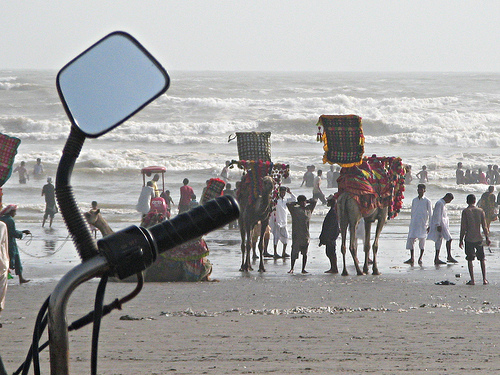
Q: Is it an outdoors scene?
A: Yes, it is outdoors.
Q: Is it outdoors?
A: Yes, it is outdoors.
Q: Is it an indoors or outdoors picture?
A: It is outdoors.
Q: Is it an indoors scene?
A: No, it is outdoors.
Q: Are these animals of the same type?
A: Yes, all the animals are camels.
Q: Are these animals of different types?
A: No, all the animals are camels.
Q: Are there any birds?
A: No, there are no birds.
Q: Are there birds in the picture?
A: No, there are no birds.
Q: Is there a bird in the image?
A: No, there are no birds.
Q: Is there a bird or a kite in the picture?
A: No, there are no birds or kites.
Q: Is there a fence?
A: No, there are no fences.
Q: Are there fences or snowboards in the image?
A: No, there are no fences or snowboards.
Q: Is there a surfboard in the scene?
A: No, there are no surfboards.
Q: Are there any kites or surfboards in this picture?
A: No, there are no surfboards or kites.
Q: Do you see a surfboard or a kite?
A: No, there are no surfboards or kites.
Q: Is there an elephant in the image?
A: No, there are no elephants.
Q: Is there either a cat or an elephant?
A: No, there are no elephants or cats.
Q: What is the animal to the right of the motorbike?
A: The animal is a camel.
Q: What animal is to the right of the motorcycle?
A: The animal is a camel.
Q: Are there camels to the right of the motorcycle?
A: Yes, there is a camel to the right of the motorcycle.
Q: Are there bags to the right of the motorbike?
A: No, there is a camel to the right of the motorbike.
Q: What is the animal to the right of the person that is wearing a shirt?
A: The animal is a camel.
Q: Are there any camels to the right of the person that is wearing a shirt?
A: Yes, there is a camel to the right of the person.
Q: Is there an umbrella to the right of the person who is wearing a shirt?
A: No, there is a camel to the right of the person.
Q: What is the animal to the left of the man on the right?
A: The animal is a camel.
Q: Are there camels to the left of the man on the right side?
A: Yes, there is a camel to the left of the man.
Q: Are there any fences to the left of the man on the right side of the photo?
A: No, there is a camel to the left of the man.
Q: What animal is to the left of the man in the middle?
A: The animal is a camel.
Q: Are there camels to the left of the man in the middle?
A: Yes, there is a camel to the left of the man.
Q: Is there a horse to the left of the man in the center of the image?
A: No, there is a camel to the left of the man.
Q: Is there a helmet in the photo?
A: No, there are no helmets.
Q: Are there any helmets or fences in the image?
A: No, there are no helmets or fences.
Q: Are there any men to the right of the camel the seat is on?
A: Yes, there is a man to the right of the camel.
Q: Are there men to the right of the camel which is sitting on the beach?
A: Yes, there is a man to the right of the camel.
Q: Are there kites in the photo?
A: No, there are no kites.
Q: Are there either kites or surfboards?
A: No, there are no kites or surfboards.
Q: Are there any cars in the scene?
A: No, there are no cars.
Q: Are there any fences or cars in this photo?
A: No, there are no cars or fences.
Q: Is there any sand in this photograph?
A: Yes, there is sand.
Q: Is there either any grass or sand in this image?
A: Yes, there is sand.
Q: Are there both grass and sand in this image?
A: No, there is sand but no grass.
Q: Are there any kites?
A: No, there are no kites.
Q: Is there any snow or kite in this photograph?
A: No, there are no kites or snow.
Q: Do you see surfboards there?
A: No, there are no surfboards.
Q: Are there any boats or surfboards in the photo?
A: No, there are no surfboards or boats.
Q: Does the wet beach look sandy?
A: Yes, the beach is sandy.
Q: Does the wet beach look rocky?
A: No, the beach is sandy.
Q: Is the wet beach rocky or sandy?
A: The beach is sandy.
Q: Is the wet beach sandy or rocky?
A: The beach is sandy.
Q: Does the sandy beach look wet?
A: Yes, the beach is wet.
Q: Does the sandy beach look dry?
A: No, the beach is wet.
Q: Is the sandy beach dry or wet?
A: The beach is wet.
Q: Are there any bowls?
A: No, there are no bowls.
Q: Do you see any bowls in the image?
A: No, there are no bowls.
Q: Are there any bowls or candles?
A: No, there are no bowls or candles.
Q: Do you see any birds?
A: No, there are no birds.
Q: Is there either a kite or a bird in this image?
A: No, there are no birds or kites.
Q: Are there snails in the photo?
A: No, there are no snails.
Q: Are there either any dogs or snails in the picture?
A: No, there are no snails or dogs.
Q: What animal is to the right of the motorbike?
A: The animal is a camel.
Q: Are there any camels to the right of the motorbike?
A: Yes, there is a camel to the right of the motorbike.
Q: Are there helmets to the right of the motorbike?
A: No, there is a camel to the right of the motorbike.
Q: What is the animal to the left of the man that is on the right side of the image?
A: The animal is a camel.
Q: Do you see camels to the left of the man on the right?
A: Yes, there is a camel to the left of the man.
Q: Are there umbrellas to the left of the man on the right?
A: No, there is a camel to the left of the man.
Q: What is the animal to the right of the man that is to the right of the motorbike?
A: The animal is a camel.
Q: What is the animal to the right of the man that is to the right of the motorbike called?
A: The animal is a camel.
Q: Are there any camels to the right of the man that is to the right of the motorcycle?
A: Yes, there is a camel to the right of the man.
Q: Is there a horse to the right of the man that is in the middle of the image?
A: No, there is a camel to the right of the man.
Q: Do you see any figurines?
A: No, there are no figurines.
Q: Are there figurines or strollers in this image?
A: No, there are no figurines or strollers.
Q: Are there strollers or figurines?
A: No, there are no figurines or strollers.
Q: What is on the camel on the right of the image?
A: The seat is on the camel.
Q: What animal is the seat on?
A: The seat is on the camel.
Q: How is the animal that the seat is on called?
A: The animal is a camel.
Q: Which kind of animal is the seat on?
A: The seat is on the camel.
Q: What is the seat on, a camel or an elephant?
A: The seat is on a camel.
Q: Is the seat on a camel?
A: Yes, the seat is on a camel.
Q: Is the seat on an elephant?
A: No, the seat is on a camel.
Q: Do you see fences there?
A: No, there are no fences.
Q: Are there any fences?
A: No, there are no fences.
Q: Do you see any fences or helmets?
A: No, there are no fences or helmets.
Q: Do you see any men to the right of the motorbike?
A: Yes, there is a man to the right of the motorbike.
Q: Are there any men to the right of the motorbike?
A: Yes, there is a man to the right of the motorbike.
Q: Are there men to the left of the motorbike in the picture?
A: No, the man is to the right of the motorbike.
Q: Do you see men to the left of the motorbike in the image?
A: No, the man is to the right of the motorbike.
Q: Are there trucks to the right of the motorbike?
A: No, there is a man to the right of the motorbike.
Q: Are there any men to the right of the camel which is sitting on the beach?
A: Yes, there is a man to the right of the camel.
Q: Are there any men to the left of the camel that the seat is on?
A: Yes, there is a man to the left of the camel.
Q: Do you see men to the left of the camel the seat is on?
A: Yes, there is a man to the left of the camel.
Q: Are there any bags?
A: No, there are no bags.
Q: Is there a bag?
A: No, there are no bags.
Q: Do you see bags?
A: No, there are no bags.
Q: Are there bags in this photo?
A: No, there are no bags.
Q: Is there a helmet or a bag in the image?
A: No, there are no bags or helmets.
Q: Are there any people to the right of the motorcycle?
A: Yes, there is a person to the right of the motorcycle.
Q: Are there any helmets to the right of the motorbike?
A: No, there is a person to the right of the motorbike.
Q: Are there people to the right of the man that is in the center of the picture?
A: Yes, there is a person to the right of the man.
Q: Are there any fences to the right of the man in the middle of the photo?
A: No, there is a person to the right of the man.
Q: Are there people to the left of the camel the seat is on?
A: Yes, there is a person to the left of the camel.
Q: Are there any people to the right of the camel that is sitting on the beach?
A: Yes, there is a person to the right of the camel.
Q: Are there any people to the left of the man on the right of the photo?
A: Yes, there is a person to the left of the man.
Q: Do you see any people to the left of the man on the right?
A: Yes, there is a person to the left of the man.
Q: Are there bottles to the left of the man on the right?
A: No, there is a person to the left of the man.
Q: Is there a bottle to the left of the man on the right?
A: No, there is a person to the left of the man.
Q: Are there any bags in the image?
A: No, there are no bags.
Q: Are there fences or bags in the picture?
A: No, there are no bags or fences.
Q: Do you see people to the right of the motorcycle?
A: Yes, there is a person to the right of the motorcycle.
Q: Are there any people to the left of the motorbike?
A: No, the person is to the right of the motorbike.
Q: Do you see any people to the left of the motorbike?
A: No, the person is to the right of the motorbike.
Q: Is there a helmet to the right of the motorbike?
A: No, there is a person to the right of the motorbike.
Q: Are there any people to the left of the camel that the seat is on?
A: Yes, there is a person to the left of the camel.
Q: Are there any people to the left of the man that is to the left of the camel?
A: Yes, there is a person to the left of the man.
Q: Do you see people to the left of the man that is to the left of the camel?
A: Yes, there is a person to the left of the man.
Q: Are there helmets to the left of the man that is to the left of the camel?
A: No, there is a person to the left of the man.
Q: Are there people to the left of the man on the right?
A: Yes, there is a person to the left of the man.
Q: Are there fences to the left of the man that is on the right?
A: No, there is a person to the left of the man.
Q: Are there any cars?
A: No, there are no cars.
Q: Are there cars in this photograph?
A: No, there are no cars.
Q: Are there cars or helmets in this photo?
A: No, there are no cars or helmets.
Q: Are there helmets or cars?
A: No, there are no cars or helmets.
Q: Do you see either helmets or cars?
A: No, there are no cars or helmets.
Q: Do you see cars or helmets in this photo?
A: No, there are no cars or helmets.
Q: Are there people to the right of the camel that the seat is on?
A: Yes, there is a person to the right of the camel.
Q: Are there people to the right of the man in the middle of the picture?
A: Yes, there is a person to the right of the man.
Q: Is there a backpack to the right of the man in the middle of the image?
A: No, there is a person to the right of the man.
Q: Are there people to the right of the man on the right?
A: Yes, there is a person to the right of the man.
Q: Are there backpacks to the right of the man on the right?
A: No, there is a person to the right of the man.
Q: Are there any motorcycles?
A: Yes, there is a motorcycle.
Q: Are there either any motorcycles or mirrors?
A: Yes, there is a motorcycle.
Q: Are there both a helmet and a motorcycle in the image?
A: No, there is a motorcycle but no helmets.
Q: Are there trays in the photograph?
A: No, there are no trays.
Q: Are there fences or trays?
A: No, there are no trays or fences.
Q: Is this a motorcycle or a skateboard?
A: This is a motorcycle.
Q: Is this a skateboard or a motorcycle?
A: This is a motorcycle.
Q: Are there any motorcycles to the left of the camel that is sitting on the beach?
A: Yes, there is a motorcycle to the left of the camel.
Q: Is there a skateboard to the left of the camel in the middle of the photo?
A: No, there is a motorcycle to the left of the camel.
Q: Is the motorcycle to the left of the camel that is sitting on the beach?
A: Yes, the motorcycle is to the left of the camel.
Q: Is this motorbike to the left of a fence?
A: No, the motorbike is to the left of the camel.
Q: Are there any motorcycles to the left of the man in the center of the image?
A: Yes, there is a motorcycle to the left of the man.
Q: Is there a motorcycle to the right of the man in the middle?
A: No, the motorcycle is to the left of the man.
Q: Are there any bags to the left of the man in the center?
A: No, there is a motorcycle to the left of the man.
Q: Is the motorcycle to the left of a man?
A: Yes, the motorcycle is to the left of a man.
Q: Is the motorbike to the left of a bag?
A: No, the motorbike is to the left of a man.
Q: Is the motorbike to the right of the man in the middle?
A: No, the motorbike is to the left of the man.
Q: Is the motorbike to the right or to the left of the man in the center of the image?
A: The motorbike is to the left of the man.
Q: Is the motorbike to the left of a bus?
A: No, the motorbike is to the left of a person.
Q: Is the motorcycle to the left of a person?
A: Yes, the motorcycle is to the left of a person.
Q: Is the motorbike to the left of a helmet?
A: No, the motorbike is to the left of a person.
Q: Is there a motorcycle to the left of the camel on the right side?
A: Yes, there is a motorcycle to the left of the camel.